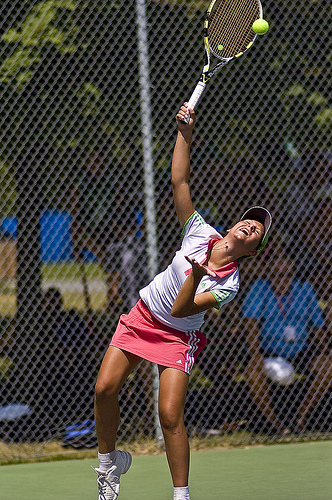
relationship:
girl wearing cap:
[89, 0, 272, 500] [233, 184, 276, 266]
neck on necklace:
[216, 233, 238, 263] [209, 243, 228, 252]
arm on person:
[150, 129, 212, 206] [99, 96, 297, 343]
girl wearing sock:
[89, 0, 272, 500] [173, 480, 190, 496]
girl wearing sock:
[89, 0, 272, 500] [96, 447, 114, 470]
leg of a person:
[149, 355, 206, 491] [90, 100, 273, 497]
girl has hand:
[89, 0, 272, 500] [175, 99, 197, 130]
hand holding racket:
[175, 99, 197, 130] [177, 0, 263, 124]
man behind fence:
[239, 253, 330, 432] [1, 5, 330, 451]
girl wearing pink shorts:
[89, 0, 272, 500] [109, 299, 208, 376]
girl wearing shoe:
[89, 0, 272, 500] [87, 444, 140, 497]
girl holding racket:
[89, 0, 272, 500] [172, 0, 266, 124]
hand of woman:
[180, 253, 223, 280] [82, 190, 280, 466]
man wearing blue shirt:
[239, 253, 330, 432] [241, 277, 324, 360]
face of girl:
[232, 219, 262, 245] [89, 0, 272, 500]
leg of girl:
[94, 345, 142, 455] [75, 96, 288, 496]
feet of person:
[89, 450, 132, 499] [90, 100, 273, 497]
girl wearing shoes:
[89, 0, 272, 500] [92, 448, 132, 498]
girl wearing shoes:
[89, 0, 272, 500] [171, 483, 189, 499]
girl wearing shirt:
[154, 97, 271, 494] [135, 208, 244, 332]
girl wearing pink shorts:
[89, 0, 272, 500] [103, 295, 208, 377]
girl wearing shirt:
[89, 0, 272, 500] [139, 210, 240, 331]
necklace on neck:
[205, 232, 245, 301] [210, 239, 237, 266]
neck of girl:
[210, 239, 237, 266] [94, 68, 285, 486]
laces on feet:
[91, 465, 109, 495] [89, 450, 132, 499]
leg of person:
[95, 345, 189, 486] [96, 1, 272, 499]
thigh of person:
[92, 340, 137, 398] [90, 100, 273, 497]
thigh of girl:
[154, 342, 194, 430] [89, 0, 272, 500]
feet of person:
[87, 450, 132, 497] [78, 95, 280, 495]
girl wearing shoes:
[89, 0, 272, 500] [93, 445, 193, 498]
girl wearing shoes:
[89, 0, 272, 500] [90, 455, 126, 499]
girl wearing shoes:
[89, 0, 272, 500] [85, 443, 130, 479]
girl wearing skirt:
[89, 0, 272, 500] [109, 299, 203, 368]